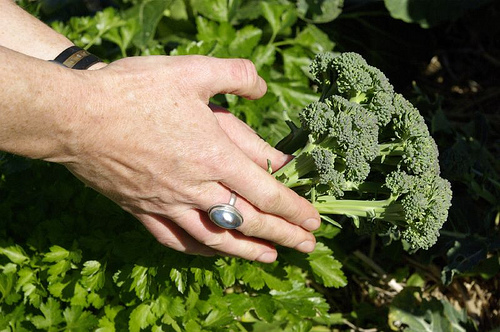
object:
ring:
[203, 193, 251, 228]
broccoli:
[268, 50, 456, 255]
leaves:
[128, 23, 202, 45]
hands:
[78, 55, 323, 263]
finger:
[185, 180, 339, 253]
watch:
[54, 43, 110, 73]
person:
[2, 0, 324, 267]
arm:
[0, 45, 78, 157]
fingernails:
[299, 215, 324, 235]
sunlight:
[249, 44, 309, 139]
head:
[307, 47, 453, 256]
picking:
[85, 44, 487, 266]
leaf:
[255, 14, 301, 71]